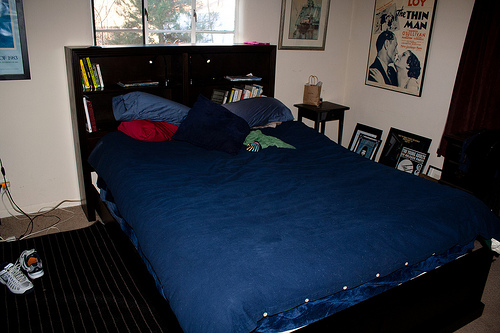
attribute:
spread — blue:
[89, 106, 497, 312]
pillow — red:
[112, 114, 184, 145]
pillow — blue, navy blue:
[167, 86, 254, 158]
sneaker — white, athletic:
[1, 242, 51, 304]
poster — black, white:
[357, 0, 445, 104]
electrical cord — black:
[0, 160, 83, 216]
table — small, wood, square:
[297, 99, 352, 143]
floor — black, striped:
[3, 223, 149, 333]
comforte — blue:
[75, 98, 499, 333]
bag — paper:
[299, 74, 328, 112]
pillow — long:
[104, 88, 192, 123]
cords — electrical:
[1, 166, 84, 245]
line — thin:
[86, 223, 145, 331]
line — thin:
[45, 232, 79, 331]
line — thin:
[61, 231, 101, 331]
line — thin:
[94, 223, 164, 331]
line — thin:
[29, 292, 45, 331]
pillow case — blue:
[109, 89, 191, 128]